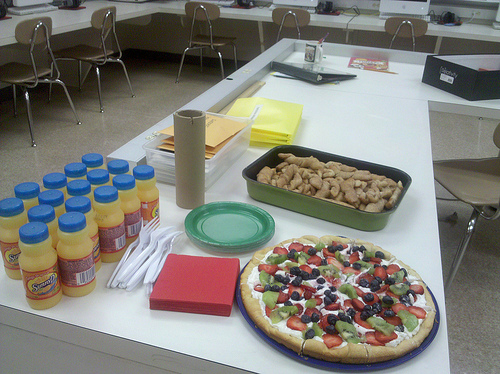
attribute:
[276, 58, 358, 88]
ring folder — black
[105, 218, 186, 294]
forks —  white, plastic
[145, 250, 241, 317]
napkins — red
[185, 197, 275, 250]
plates — green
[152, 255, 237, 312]
napkins — red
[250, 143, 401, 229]
pan — oblong , green, brown 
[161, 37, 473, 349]
desk — White l-shaped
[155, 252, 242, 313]
napkins — red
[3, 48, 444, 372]
table — white 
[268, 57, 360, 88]
binder — Black ring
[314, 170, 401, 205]
chicken — breaded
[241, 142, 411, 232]
pan — Long green 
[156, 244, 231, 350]
napkins — red, Pile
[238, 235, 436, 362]
pizza — kiwi slices, strawberry, blueberries, large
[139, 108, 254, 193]
bin — plastic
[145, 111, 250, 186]
bucket — plastic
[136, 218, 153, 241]
fork — plastic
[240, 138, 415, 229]
dish — green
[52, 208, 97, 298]
bottle — sunny d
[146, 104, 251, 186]
bin — Plastic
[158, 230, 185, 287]
fork — white, plastic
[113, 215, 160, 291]
fork — white, plastic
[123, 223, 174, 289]
fork — white, plastic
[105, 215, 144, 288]
fork — white, plastic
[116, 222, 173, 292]
fork — white, plastic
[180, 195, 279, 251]
plates — green, small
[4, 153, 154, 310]
bottles — plastic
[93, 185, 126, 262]
bottle — sunny d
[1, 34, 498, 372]
table — white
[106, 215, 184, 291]
forks — white, plastic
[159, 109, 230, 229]
towels — brown, paper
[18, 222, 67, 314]
bottle — small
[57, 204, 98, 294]
bottle — small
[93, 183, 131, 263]
bottle — small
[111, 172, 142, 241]
bottle — small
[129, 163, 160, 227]
bottle — small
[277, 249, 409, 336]
toppings — strawberries, kiwi, blueberries 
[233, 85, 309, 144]
binder — yellow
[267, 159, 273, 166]
interior — black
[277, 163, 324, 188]
tenders — chicken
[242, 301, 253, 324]
plate —  blue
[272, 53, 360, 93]
binder — paper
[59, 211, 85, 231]
caps — blue 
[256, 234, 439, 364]
pizza — dessert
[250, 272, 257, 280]
topping — creamy 